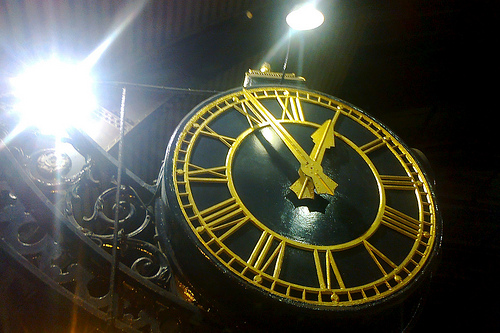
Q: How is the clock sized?
A: Large.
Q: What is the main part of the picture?
A: A clock.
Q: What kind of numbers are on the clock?
A: Roman numerals.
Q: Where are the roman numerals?
A: Around the clock.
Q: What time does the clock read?
A: 12:55.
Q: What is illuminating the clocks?
A: Lights.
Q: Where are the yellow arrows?
A: On the clock.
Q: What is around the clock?
A: Decorative metal.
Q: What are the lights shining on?
A: A large clock.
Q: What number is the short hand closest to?
A: 1.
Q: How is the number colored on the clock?
A: Gold.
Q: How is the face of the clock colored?
A: Black.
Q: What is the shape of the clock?
A: Round.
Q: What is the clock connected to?
A: A black object.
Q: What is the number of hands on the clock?
A: Two.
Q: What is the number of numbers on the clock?
A: 12.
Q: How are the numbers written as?
A: Roman numerals.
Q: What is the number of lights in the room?
A: Two.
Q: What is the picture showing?
A: A clock.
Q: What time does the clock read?
A: 1:55.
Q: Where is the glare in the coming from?
A: The light.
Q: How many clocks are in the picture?
A: One.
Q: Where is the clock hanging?
A: From the ceiling.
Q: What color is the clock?
A: Black and gold.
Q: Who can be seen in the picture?
A: No one.